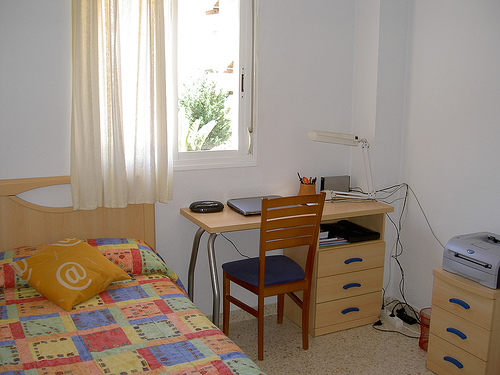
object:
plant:
[176, 68, 232, 152]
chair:
[220, 192, 326, 361]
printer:
[440, 230, 498, 290]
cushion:
[220, 254, 305, 288]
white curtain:
[70, 1, 180, 210]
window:
[163, 1, 253, 164]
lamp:
[306, 129, 375, 203]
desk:
[180, 191, 394, 338]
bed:
[0, 176, 268, 374]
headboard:
[0, 174, 157, 249]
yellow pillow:
[8, 235, 131, 313]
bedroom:
[0, 0, 498, 374]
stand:
[424, 266, 499, 374]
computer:
[226, 194, 302, 218]